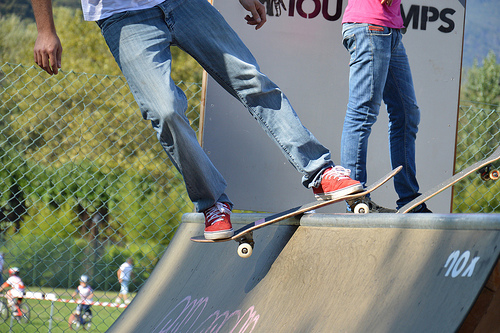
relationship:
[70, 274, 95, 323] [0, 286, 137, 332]
child on top of grass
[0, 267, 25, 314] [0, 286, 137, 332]
child on top of grass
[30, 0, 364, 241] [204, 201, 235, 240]
boy wearing shoe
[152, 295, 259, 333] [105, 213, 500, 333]
writing on ramp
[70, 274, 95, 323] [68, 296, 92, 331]
child riding bike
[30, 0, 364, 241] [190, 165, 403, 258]
boy riding skateboard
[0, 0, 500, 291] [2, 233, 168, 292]
trees are behind fence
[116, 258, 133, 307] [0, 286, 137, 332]
man walking on grass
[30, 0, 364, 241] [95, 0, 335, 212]
boy wearing jeans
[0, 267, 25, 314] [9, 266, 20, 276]
child wearing helmet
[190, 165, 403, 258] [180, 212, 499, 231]
skateboard grinding rail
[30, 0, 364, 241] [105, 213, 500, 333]
boy skating on ramp